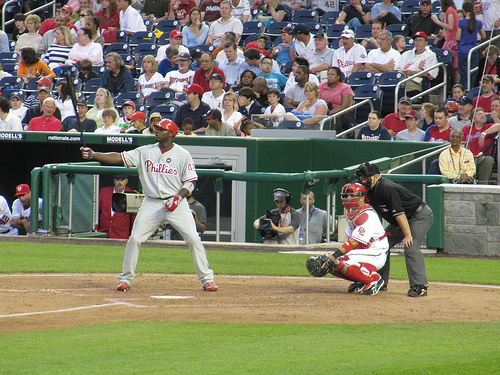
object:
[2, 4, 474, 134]
fans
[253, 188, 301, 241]
man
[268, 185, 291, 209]
headphones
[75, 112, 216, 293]
player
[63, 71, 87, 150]
bat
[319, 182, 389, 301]
catcher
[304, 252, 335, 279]
mitt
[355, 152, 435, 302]
umpire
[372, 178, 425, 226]
black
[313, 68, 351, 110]
fan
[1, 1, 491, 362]
stadium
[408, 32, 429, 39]
cap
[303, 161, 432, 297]
men playing baseball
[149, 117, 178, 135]
player in red helmet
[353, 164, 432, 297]
catcher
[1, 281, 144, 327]
white lines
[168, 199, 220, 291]
right leg of a man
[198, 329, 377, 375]
section of a lawn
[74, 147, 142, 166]
arm of a man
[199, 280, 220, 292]
shoe of a man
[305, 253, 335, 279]
black base ball bat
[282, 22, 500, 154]
people looking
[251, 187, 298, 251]
camera man standing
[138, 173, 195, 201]
part of a jersey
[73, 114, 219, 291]
playing baseball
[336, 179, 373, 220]
red helmet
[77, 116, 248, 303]
white uniform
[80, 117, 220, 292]
team is phillies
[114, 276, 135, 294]
red shoe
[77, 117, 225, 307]
man has dark skin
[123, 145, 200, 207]
shirt says phillies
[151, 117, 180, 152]
helmet is red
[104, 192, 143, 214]
camera is recording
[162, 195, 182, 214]
baseball glove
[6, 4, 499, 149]
watching the game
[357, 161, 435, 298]
squatting down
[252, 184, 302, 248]
recording the game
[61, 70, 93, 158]
holding a bat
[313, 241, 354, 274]
catcher's mitt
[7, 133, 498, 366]
baseball stadium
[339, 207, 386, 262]
white shirt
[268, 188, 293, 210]
wearing earphones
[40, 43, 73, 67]
blue and white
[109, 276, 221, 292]
red baseball shoes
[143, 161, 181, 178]
phillies logo